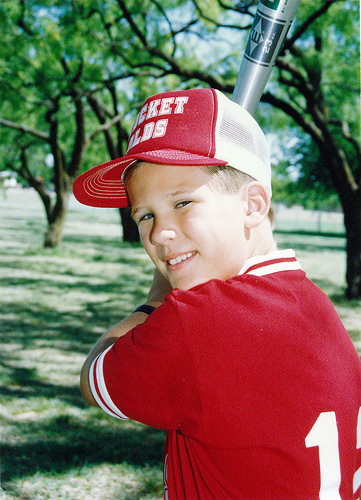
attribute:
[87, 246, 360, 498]
shirt — red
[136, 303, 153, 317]
band — black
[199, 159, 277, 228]
hair — blonde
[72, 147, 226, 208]
bill — red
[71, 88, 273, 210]
cap — red, white, baseball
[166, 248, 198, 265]
teeth — white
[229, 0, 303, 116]
bat — silver, aluminum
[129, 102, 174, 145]
writing — white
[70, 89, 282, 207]
hat — red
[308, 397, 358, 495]
numbers — white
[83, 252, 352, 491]
jersey — back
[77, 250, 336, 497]
jersey — baseball, red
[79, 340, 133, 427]
trim — white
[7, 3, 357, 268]
trees — three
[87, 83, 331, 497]
player — baseball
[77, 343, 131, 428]
stripe — white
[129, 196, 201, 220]
eyes — boy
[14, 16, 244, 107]
trees — shadows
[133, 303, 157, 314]
tape — black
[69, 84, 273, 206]
ball cap — red and white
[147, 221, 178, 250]
nose — human